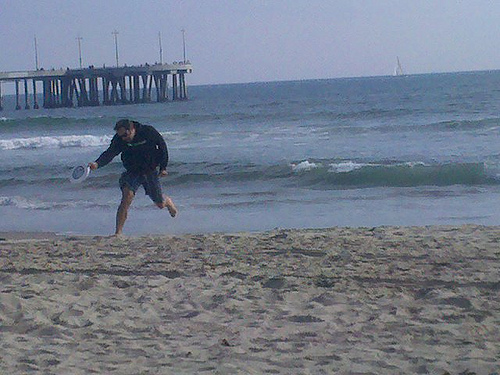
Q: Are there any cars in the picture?
A: No, there are no cars.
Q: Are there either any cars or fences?
A: No, there are no cars or fences.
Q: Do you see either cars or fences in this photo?
A: No, there are no cars or fences.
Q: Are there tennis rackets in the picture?
A: No, there are no tennis rackets.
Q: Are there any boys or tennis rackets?
A: No, there are no tennis rackets or boys.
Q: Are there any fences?
A: No, there are no fences.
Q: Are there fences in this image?
A: No, there are no fences.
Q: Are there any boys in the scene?
A: No, there are no boys.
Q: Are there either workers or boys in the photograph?
A: No, there are no boys or workers.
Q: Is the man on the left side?
A: Yes, the man is on the left of the image.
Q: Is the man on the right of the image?
A: No, the man is on the left of the image.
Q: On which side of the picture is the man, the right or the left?
A: The man is on the left of the image.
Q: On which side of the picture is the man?
A: The man is on the left of the image.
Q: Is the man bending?
A: Yes, the man is bending.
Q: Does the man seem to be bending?
A: Yes, the man is bending.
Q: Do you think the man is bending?
A: Yes, the man is bending.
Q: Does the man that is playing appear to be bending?
A: Yes, the man is bending.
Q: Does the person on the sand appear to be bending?
A: Yes, the man is bending.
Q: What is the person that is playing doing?
A: The man is bending.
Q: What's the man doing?
A: The man is bending.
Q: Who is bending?
A: The man is bending.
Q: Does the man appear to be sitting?
A: No, the man is bending.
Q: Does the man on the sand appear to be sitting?
A: No, the man is bending.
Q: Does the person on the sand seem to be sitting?
A: No, the man is bending.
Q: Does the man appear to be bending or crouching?
A: The man is bending.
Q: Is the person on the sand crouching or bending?
A: The man is bending.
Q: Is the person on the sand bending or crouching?
A: The man is bending.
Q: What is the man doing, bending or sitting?
A: The man is bending.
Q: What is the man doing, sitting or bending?
A: The man is bending.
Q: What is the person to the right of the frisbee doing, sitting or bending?
A: The man is bending.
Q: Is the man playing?
A: Yes, the man is playing.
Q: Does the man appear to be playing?
A: Yes, the man is playing.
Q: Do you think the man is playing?
A: Yes, the man is playing.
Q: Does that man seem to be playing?
A: Yes, the man is playing.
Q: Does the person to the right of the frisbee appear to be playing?
A: Yes, the man is playing.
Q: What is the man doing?
A: The man is playing.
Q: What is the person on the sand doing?
A: The man is playing.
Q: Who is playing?
A: The man is playing.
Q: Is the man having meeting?
A: No, the man is playing.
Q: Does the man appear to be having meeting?
A: No, the man is playing.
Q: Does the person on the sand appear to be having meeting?
A: No, the man is playing.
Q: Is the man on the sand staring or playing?
A: The man is playing.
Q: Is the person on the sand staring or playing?
A: The man is playing.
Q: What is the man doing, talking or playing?
A: The man is playing.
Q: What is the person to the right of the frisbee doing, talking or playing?
A: The man is playing.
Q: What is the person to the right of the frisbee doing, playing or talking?
A: The man is playing.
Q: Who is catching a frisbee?
A: The man is catching a frisbee.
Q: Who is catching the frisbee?
A: The man is catching a frisbee.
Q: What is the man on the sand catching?
A: The man is catching a frisbee.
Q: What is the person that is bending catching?
A: The man is catching a frisbee.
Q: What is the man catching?
A: The man is catching a frisbee.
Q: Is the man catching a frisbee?
A: Yes, the man is catching a frisbee.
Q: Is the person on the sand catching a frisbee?
A: Yes, the man is catching a frisbee.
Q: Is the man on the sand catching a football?
A: No, the man is catching a frisbee.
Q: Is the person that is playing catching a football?
A: No, the man is catching a frisbee.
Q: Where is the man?
A: The man is on the sand.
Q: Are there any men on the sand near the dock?
A: Yes, there is a man on the sand.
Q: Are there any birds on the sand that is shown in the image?
A: No, there is a man on the sand.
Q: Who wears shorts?
A: The man wears shorts.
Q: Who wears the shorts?
A: The man wears shorts.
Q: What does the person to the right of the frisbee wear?
A: The man wears shorts.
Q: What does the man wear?
A: The man wears shorts.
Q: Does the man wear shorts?
A: Yes, the man wears shorts.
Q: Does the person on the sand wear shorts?
A: Yes, the man wears shorts.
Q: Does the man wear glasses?
A: No, the man wears shorts.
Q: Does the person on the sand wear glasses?
A: No, the man wears shorts.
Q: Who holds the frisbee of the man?
A: The man holds the frisbee.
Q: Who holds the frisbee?
A: The man holds the frisbee.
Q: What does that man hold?
A: The man holds the frisbee.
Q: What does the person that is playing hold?
A: The man holds the frisbee.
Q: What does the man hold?
A: The man holds the frisbee.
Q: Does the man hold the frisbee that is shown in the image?
A: Yes, the man holds the frisbee.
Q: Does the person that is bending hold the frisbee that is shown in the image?
A: Yes, the man holds the frisbee.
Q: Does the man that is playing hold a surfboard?
A: No, the man holds the frisbee.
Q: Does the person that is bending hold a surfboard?
A: No, the man holds the frisbee.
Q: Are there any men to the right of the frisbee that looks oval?
A: Yes, there is a man to the right of the frisbee.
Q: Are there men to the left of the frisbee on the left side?
A: No, the man is to the right of the frisbee.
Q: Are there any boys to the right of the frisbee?
A: No, there is a man to the right of the frisbee.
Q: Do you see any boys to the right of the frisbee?
A: No, there is a man to the right of the frisbee.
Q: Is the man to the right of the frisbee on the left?
A: Yes, the man is to the right of the frisbee.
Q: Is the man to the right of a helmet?
A: No, the man is to the right of the frisbee.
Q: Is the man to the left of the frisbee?
A: No, the man is to the right of the frisbee.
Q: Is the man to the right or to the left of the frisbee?
A: The man is to the right of the frisbee.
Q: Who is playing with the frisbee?
A: The man is playing with the frisbee.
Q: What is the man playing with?
A: The man is playing with a frisbee.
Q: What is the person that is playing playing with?
A: The man is playing with a frisbee.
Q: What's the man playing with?
A: The man is playing with a frisbee.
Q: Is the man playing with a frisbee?
A: Yes, the man is playing with a frisbee.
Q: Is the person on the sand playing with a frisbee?
A: Yes, the man is playing with a frisbee.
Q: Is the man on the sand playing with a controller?
A: No, the man is playing with a frisbee.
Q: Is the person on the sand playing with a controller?
A: No, the man is playing with a frisbee.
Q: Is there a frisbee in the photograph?
A: Yes, there is a frisbee.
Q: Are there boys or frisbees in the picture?
A: Yes, there is a frisbee.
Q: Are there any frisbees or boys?
A: Yes, there is a frisbee.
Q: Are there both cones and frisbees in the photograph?
A: No, there is a frisbee but no cones.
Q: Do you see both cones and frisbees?
A: No, there is a frisbee but no cones.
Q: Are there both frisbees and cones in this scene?
A: No, there is a frisbee but no cones.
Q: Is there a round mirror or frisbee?
A: Yes, there is a round frisbee.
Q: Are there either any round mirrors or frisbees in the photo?
A: Yes, there is a round frisbee.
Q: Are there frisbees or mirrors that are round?
A: Yes, the frisbee is round.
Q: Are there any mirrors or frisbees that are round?
A: Yes, the frisbee is round.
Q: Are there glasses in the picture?
A: No, there are no glasses.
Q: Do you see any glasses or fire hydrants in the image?
A: No, there are no glasses or fire hydrants.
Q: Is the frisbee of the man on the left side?
A: Yes, the frisbee is on the left of the image.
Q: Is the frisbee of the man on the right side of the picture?
A: No, the frisbee is on the left of the image.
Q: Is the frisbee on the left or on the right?
A: The frisbee is on the left of the image.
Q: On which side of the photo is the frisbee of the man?
A: The frisbee is on the left of the image.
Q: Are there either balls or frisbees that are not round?
A: No, there is a frisbee but it is round.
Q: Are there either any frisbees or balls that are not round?
A: No, there is a frisbee but it is round.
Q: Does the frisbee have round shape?
A: Yes, the frisbee is round.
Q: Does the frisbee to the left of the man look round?
A: Yes, the frisbee is round.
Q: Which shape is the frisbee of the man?
A: The frisbee is round.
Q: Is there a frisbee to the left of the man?
A: Yes, there is a frisbee to the left of the man.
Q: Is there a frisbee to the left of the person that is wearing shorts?
A: Yes, there is a frisbee to the left of the man.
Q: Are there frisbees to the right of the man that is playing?
A: No, the frisbee is to the left of the man.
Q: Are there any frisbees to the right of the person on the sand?
A: No, the frisbee is to the left of the man.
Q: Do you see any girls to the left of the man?
A: No, there is a frisbee to the left of the man.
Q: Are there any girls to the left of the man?
A: No, there is a frisbee to the left of the man.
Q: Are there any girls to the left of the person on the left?
A: No, there is a frisbee to the left of the man.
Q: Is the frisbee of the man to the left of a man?
A: Yes, the frisbee is to the left of a man.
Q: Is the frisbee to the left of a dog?
A: No, the frisbee is to the left of a man.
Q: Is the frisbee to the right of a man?
A: No, the frisbee is to the left of a man.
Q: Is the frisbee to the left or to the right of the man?
A: The frisbee is to the left of the man.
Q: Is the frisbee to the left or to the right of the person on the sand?
A: The frisbee is to the left of the man.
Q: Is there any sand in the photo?
A: Yes, there is sand.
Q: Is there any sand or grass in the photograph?
A: Yes, there is sand.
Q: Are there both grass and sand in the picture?
A: No, there is sand but no grass.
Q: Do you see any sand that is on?
A: Yes, there is sand that is on.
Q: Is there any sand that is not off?
A: Yes, there is sand that is on.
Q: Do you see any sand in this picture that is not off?
A: Yes, there is sand that is on .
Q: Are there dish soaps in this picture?
A: No, there are no dish soaps.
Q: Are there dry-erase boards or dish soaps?
A: No, there are no dish soaps or dry-erase boards.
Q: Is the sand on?
A: Yes, the sand is on.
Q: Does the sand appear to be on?
A: Yes, the sand is on.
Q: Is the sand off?
A: No, the sand is on.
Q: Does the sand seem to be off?
A: No, the sand is on.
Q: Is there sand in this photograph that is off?
A: No, there is sand but it is on.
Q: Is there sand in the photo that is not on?
A: No, there is sand but it is on.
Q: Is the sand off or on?
A: The sand is on.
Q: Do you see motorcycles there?
A: No, there are no motorcycles.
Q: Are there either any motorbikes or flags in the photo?
A: No, there are no motorbikes or flags.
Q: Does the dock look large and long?
A: Yes, the dock is large and long.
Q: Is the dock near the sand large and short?
A: No, the pier is large but long.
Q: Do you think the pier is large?
A: Yes, the pier is large.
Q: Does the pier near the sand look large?
A: Yes, the dock is large.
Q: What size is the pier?
A: The pier is large.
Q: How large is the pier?
A: The pier is large.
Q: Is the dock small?
A: No, the dock is large.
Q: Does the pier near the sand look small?
A: No, the dock is large.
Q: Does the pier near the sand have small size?
A: No, the dock is large.